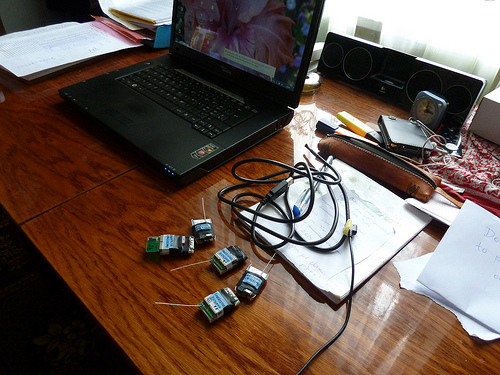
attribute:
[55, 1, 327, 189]
laptop — black, existing, on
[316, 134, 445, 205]
case — pencil case, brown, existing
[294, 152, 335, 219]
pen — blue, white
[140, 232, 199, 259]
gizmo — electrical, small, green, black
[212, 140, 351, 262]
cable — black, existing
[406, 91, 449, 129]
clock — blue, existing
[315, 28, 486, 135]
speaker — black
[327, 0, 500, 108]
sheers — opaque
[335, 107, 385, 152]
highlighter — yellow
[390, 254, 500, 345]
paper — torn, white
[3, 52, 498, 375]
surface — wood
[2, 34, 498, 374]
desk — existing, wooden, brown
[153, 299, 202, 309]
straw — white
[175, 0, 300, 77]
flower — pink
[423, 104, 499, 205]
cloth — red, white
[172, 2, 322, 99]
screen — on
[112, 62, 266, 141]
keyboard — existing